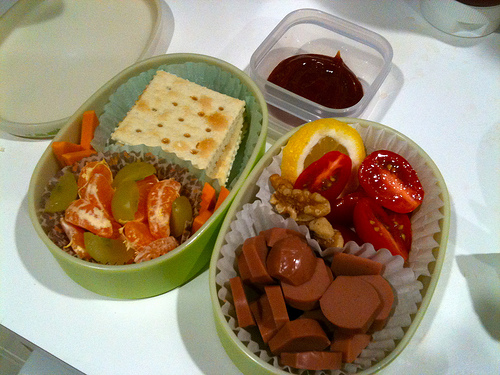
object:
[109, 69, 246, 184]
crackers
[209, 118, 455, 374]
cup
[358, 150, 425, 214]
tomatoes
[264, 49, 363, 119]
ketchup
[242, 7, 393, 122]
container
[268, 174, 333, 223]
nuts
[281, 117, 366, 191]
lemon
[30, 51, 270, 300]
bowl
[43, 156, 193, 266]
grapes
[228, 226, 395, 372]
hot dogs